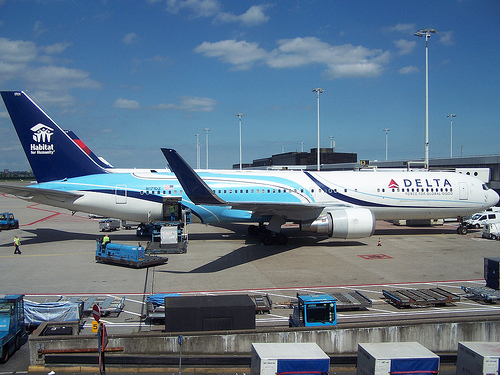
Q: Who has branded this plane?
A: Delta.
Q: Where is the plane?
A: Sitting on the tarmac.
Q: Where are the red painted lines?
A: Behind the plane on the tarmac.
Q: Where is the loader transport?
A: Under and behind the plane's right wing.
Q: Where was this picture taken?
A: An airport.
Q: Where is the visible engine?
A: Under the wing.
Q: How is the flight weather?
A: Clear sky with slight cloud coverage.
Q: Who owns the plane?
A: Delta Airlines.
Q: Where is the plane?
A: On tarmac.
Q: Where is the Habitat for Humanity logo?
A: Plane's tail.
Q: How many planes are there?
A: One.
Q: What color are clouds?
A: White.